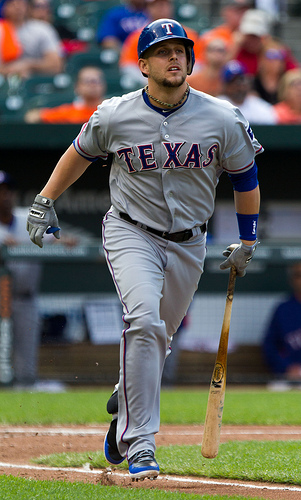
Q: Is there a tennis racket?
A: No, there are no rackets.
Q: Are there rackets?
A: No, there are no rackets.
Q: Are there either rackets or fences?
A: No, there are no rackets or fences.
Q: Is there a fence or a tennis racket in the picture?
A: No, there are no rackets or fences.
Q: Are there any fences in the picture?
A: No, there are no fences.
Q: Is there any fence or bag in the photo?
A: No, there are no fences or bags.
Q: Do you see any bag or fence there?
A: No, there are no fences or bags.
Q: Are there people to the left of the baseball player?
A: Yes, there is a person to the left of the player.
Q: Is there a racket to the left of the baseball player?
A: No, there is a person to the left of the player.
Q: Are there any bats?
A: Yes, there is a bat.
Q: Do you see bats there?
A: Yes, there is a bat.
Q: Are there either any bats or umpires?
A: Yes, there is a bat.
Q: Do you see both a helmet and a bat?
A: Yes, there are both a bat and a helmet.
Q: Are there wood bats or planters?
A: Yes, there is a wood bat.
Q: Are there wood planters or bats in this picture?
A: Yes, there is a wood bat.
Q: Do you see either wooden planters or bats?
A: Yes, there is a wood bat.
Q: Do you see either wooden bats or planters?
A: Yes, there is a wood bat.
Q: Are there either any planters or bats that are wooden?
A: Yes, the bat is wooden.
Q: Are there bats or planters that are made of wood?
A: Yes, the bat is made of wood.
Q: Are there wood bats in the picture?
A: Yes, there is a wood bat.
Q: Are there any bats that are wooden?
A: Yes, there is a bat that is wooden.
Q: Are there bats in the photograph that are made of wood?
A: Yes, there is a bat that is made of wood.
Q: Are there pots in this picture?
A: No, there are no pots.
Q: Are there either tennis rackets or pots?
A: No, there are no pots or tennis rackets.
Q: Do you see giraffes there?
A: No, there are no giraffes.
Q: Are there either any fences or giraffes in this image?
A: No, there are no giraffes or fences.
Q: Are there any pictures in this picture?
A: No, there are no pictures.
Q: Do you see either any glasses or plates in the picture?
A: No, there are no glasses or plates.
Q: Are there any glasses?
A: No, there are no glasses.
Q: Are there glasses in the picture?
A: No, there are no glasses.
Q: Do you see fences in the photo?
A: No, there are no fences.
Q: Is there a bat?
A: Yes, there is a bat.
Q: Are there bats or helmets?
A: Yes, there is a bat.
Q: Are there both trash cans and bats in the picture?
A: No, there is a bat but no trash cans.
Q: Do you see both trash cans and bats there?
A: No, there is a bat but no trash cans.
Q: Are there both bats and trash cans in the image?
A: No, there is a bat but no trash cans.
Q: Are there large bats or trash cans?
A: Yes, there is a large bat.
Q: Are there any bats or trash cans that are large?
A: Yes, the bat is large.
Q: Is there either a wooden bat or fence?
A: Yes, there is a wood bat.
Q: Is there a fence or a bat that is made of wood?
A: Yes, the bat is made of wood.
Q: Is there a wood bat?
A: Yes, there is a bat that is made of wood.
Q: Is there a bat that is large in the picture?
A: Yes, there is a large bat.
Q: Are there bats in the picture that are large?
A: Yes, there is a bat that is large.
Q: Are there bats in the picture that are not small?
A: Yes, there is a large bat.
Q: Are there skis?
A: No, there are no skis.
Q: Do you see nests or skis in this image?
A: No, there are no skis or nests.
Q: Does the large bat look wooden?
A: Yes, the bat is wooden.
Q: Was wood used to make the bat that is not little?
A: Yes, the bat is made of wood.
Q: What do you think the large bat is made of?
A: The bat is made of wood.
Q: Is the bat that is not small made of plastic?
A: No, the bat is made of wood.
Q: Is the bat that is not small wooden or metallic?
A: The bat is wooden.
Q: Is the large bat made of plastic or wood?
A: The bat is made of wood.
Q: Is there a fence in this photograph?
A: No, there are no fences.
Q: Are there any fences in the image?
A: No, there are no fences.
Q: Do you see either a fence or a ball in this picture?
A: No, there are no fences or balls.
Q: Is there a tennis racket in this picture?
A: No, there are no rackets.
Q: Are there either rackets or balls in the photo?
A: No, there are no rackets or balls.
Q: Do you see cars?
A: No, there are no cars.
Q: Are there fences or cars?
A: No, there are no cars or fences.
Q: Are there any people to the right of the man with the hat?
A: Yes, there is a person to the right of the man.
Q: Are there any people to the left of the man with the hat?
A: No, the person is to the right of the man.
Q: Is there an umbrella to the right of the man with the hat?
A: No, there is a person to the right of the man.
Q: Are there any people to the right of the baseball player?
A: Yes, there is a person to the right of the player.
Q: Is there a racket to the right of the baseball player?
A: No, there is a person to the right of the player.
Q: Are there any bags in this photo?
A: No, there are no bags.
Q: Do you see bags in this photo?
A: No, there are no bags.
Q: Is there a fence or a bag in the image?
A: No, there are no bags or fences.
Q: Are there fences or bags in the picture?
A: No, there are no bags or fences.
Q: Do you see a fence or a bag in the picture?
A: No, there are no bags or fences.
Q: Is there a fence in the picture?
A: No, there are no fences.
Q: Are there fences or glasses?
A: No, there are no fences or glasses.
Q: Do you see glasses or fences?
A: No, there are no fences or glasses.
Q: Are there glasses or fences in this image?
A: No, there are no fences or glasses.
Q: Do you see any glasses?
A: No, there are no glasses.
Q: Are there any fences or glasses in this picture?
A: No, there are no glasses or fences.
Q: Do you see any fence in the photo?
A: No, there are no fences.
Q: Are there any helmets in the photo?
A: Yes, there is a helmet.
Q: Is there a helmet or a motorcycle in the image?
A: Yes, there is a helmet.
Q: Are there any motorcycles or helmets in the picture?
A: Yes, there is a helmet.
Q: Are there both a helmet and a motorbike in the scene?
A: No, there is a helmet but no motorcycles.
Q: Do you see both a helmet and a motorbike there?
A: No, there is a helmet but no motorcycles.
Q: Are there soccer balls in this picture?
A: No, there are no soccer balls.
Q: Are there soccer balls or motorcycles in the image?
A: No, there are no soccer balls or motorcycles.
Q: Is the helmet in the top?
A: Yes, the helmet is in the top of the image.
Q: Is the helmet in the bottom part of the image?
A: No, the helmet is in the top of the image.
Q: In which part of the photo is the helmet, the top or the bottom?
A: The helmet is in the top of the image.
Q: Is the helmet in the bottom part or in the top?
A: The helmet is in the top of the image.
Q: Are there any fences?
A: No, there are no fences.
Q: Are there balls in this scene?
A: No, there are no balls.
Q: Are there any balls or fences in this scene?
A: No, there are no balls or fences.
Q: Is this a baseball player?
A: Yes, this is a baseball player.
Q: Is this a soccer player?
A: No, this is a baseball player.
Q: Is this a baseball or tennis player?
A: This is a baseball player.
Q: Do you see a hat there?
A: Yes, there is a hat.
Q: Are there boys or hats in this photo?
A: Yes, there is a hat.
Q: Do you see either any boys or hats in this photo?
A: Yes, there is a hat.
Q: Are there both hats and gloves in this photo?
A: Yes, there are both a hat and gloves.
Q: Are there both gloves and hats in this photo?
A: Yes, there are both a hat and gloves.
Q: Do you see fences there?
A: No, there are no fences.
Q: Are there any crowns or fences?
A: No, there are no fences or crowns.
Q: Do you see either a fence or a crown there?
A: No, there are no fences or crowns.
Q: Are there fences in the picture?
A: No, there are no fences.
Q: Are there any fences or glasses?
A: No, there are no fences or glasses.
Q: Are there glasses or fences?
A: No, there are no fences or glasses.